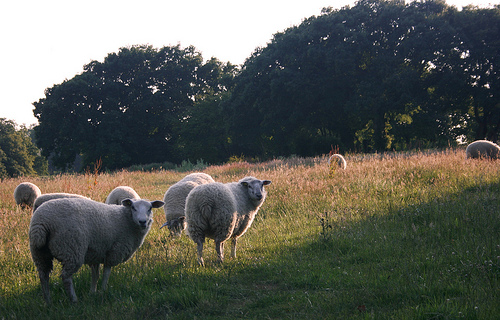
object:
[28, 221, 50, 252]
tail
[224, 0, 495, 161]
tree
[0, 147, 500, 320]
field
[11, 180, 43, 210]
sheep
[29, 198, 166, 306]
sheep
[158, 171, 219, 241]
sheep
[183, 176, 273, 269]
sheep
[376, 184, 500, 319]
grass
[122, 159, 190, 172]
bush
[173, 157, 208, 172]
weeds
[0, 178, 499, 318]
shadows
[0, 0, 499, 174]
trees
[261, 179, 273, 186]
ears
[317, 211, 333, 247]
flower patch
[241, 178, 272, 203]
head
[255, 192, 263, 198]
nose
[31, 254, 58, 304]
legs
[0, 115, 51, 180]
tree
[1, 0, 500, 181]
wooded area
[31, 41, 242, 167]
tree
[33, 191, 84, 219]
sheep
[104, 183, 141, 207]
sheep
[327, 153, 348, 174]
sheep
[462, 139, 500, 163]
sheep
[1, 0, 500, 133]
sky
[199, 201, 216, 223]
tail